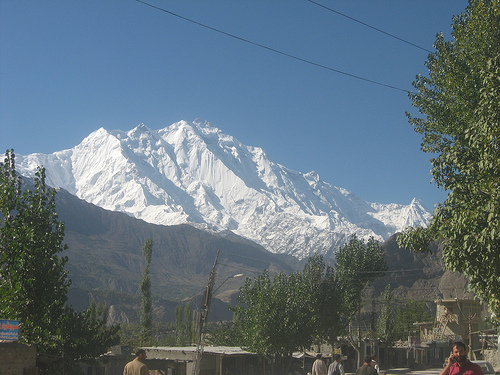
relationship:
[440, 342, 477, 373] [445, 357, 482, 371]
man in shirt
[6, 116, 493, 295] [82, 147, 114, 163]
mountain covered in snow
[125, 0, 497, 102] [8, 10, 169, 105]
lines against sky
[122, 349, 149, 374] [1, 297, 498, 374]
man in a village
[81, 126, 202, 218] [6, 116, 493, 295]
snow on mountain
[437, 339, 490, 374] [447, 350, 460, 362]
man on phone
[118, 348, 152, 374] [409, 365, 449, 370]
man on street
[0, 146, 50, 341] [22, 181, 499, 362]
tree against mountain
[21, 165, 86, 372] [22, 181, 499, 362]
tree against mountain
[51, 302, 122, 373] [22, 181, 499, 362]
tree against mountain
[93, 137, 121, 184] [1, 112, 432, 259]
snow on mountain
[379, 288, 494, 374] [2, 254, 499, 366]
building in town